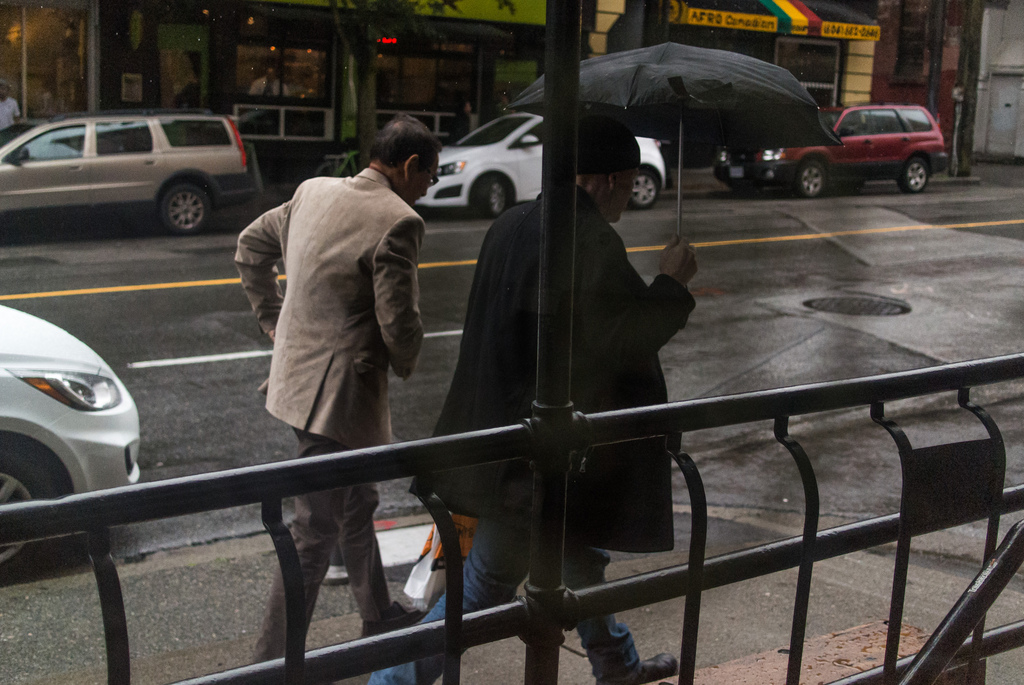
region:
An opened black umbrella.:
[506, 39, 842, 156]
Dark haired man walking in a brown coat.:
[235, 105, 438, 666]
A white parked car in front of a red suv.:
[414, 111, 667, 216]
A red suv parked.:
[712, 102, 951, 191]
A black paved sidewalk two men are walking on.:
[4, 506, 899, 683]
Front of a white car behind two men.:
[1, 302, 141, 563]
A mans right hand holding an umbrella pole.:
[661, 235, 699, 289]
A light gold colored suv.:
[3, 114, 261, 233]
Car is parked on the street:
[0, 303, 149, 572]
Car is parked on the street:
[0, 110, 257, 232]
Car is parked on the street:
[416, 111, 667, 207]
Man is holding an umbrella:
[513, 38, 837, 247]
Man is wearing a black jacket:
[409, 187, 695, 552]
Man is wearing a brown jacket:
[234, 168, 428, 438]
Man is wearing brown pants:
[253, 439, 394, 664]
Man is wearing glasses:
[402, 155, 445, 184]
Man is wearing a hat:
[551, 108, 640, 172]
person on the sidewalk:
[234, 118, 438, 653]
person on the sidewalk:
[415, 121, 692, 682]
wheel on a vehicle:
[157, 176, 209, 234]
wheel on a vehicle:
[0, 434, 73, 575]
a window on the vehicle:
[176, 120, 225, 149]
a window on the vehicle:
[111, 123, 140, 166]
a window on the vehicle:
[15, 116, 53, 168]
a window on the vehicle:
[448, 119, 483, 138]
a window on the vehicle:
[843, 114, 848, 127]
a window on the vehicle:
[871, 103, 891, 142]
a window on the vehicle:
[901, 103, 949, 142]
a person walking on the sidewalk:
[597, 13, 820, 539]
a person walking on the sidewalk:
[217, 84, 465, 606]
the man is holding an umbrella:
[511, 35, 843, 323]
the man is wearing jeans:
[389, 497, 649, 678]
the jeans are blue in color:
[366, 511, 639, 682]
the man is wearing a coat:
[410, 192, 687, 550]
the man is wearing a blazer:
[236, 168, 426, 435]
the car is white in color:
[3, 301, 143, 555]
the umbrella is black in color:
[515, 37, 839, 287]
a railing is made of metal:
[8, 357, 1021, 681]